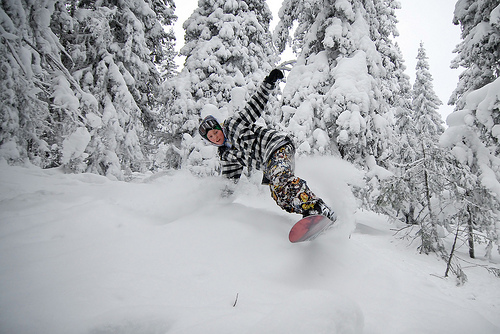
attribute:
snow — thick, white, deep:
[59, 200, 168, 296]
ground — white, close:
[218, 240, 441, 318]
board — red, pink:
[291, 215, 332, 260]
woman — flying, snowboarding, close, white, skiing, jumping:
[177, 98, 321, 204]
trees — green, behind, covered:
[200, 6, 384, 58]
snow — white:
[2, 4, 484, 315]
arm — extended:
[224, 67, 286, 122]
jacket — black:
[218, 81, 292, 206]